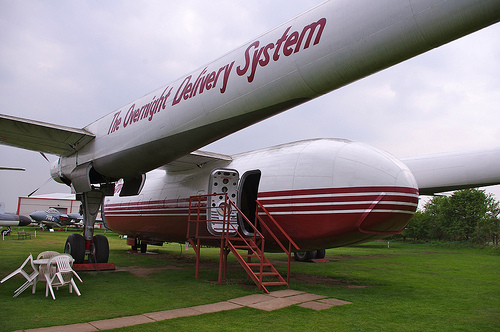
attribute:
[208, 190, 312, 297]
ladder — small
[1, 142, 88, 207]
propellor — still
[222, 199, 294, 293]
steps — red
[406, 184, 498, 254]
trees — green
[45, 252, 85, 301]
chair — white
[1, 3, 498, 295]
plane — red, white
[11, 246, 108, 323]
table — white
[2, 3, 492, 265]
plane — white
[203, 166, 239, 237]
door — open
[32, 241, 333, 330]
path — red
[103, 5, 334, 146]
words — The Overnight Delivery System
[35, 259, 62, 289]
table — plastic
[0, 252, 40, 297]
chairs — plastic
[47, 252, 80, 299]
chairs — plastic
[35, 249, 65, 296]
chairs — plastic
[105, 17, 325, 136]
words — The Overnight Delivery System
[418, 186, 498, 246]
bush — green, leafy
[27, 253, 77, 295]
table — small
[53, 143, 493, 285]
plane — cargo plane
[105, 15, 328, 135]
advertisement — free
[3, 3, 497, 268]
airplane — red, white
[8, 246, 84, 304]
chairs — plastic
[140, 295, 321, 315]
walkway — stepping stone